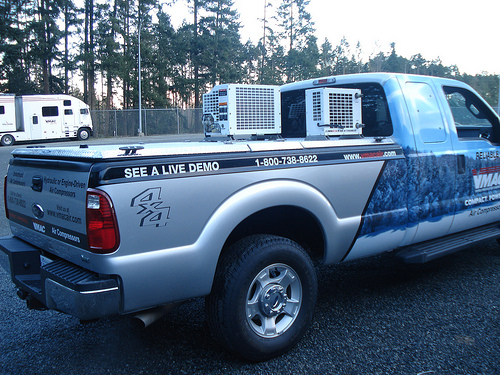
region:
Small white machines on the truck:
[190, 76, 369, 145]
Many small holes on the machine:
[239, 87, 277, 137]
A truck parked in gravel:
[18, 58, 481, 363]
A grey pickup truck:
[30, 75, 477, 349]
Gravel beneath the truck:
[337, 270, 479, 359]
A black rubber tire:
[223, 240, 316, 357]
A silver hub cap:
[250, 266, 303, 332]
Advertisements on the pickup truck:
[93, 150, 385, 179]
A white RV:
[0, 90, 103, 145]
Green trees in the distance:
[53, 15, 293, 78]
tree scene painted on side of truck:
[362, 140, 486, 239]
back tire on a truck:
[215, 233, 349, 373]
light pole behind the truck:
[127, 8, 155, 141]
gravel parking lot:
[336, 295, 483, 359]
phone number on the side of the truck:
[246, 155, 326, 170]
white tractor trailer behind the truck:
[7, 75, 101, 145]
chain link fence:
[99, 100, 187, 139]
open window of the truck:
[437, 79, 497, 141]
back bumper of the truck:
[3, 227, 130, 334]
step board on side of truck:
[397, 227, 493, 261]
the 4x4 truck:
[5, 72, 497, 356]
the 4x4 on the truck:
[130, 185, 175, 230]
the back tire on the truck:
[218, 235, 320, 357]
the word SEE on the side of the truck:
[117, 157, 222, 179]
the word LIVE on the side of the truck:
[160, 163, 190, 175]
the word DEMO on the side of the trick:
[188, 157, 221, 175]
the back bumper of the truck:
[0, 230, 120, 318]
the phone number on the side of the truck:
[247, 155, 322, 166]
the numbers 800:
[262, 155, 280, 170]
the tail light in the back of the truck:
[81, 183, 118, 254]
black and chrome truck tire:
[214, 245, 326, 357]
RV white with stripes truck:
[0, 88, 103, 151]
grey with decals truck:
[47, 76, 498, 342]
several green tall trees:
[70, 13, 211, 102]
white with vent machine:
[180, 79, 294, 151]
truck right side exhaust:
[109, 271, 197, 338]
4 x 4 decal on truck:
[127, 187, 184, 239]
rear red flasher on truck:
[74, 190, 131, 261]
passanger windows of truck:
[390, 68, 496, 153]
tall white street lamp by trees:
[112, 8, 162, 139]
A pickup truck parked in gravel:
[20, 57, 480, 358]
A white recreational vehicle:
[0, 97, 119, 144]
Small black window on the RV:
[34, 98, 79, 118]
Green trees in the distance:
[42, 0, 206, 82]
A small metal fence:
[102, 105, 207, 137]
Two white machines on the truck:
[204, 82, 367, 142]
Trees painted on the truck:
[377, 166, 465, 225]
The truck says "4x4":
[120, 187, 179, 234]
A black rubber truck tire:
[212, 245, 319, 354]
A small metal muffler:
[130, 305, 185, 333]